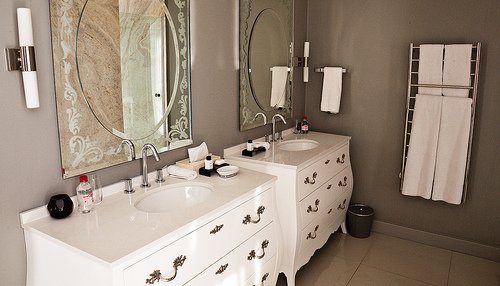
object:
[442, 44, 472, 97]
towel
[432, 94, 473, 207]
towel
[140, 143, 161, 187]
faucet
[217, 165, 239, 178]
soap dish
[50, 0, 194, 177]
mirror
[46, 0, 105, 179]
pattern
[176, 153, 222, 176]
box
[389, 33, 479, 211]
wood cabinets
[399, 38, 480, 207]
towel rack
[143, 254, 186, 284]
silver handle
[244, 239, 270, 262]
silver handle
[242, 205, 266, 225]
silver handle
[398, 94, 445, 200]
towels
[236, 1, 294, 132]
mirror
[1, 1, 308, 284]
wall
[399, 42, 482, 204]
rack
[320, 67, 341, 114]
towel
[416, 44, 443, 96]
towel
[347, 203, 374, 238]
bin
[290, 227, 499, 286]
floor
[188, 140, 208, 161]
tissues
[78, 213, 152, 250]
counter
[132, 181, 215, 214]
sink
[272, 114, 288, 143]
facet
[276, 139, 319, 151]
sink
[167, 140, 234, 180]
tissues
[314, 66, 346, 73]
holder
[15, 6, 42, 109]
lamp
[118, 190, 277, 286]
drawers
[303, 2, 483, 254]
wall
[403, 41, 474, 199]
towels